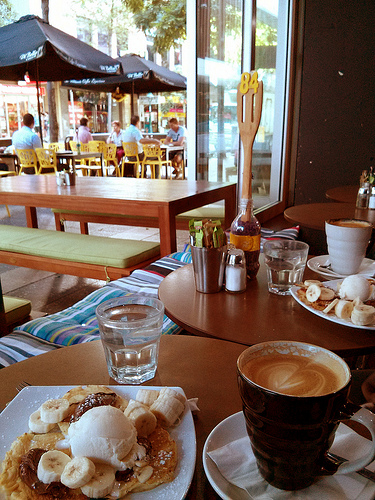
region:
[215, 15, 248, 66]
part of a window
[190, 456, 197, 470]
dgge of a plate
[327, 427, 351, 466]
part of a handle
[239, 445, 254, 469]
aprt of a cloth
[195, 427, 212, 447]
edge of a dish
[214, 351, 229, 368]
part of a table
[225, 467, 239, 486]
edge of a cloth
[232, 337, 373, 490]
A dark coffee mug with light handle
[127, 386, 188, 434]
Banana slices on a white plate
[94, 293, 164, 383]
A clear glass filled with water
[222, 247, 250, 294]
A glass salt shaker with a metal lid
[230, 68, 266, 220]
A tall wood spatula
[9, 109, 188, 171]
People sitting in the background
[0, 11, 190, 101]
A pair of black umbrellas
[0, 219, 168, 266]
A light green cushion on a bench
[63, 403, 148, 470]
A dollop of ice cream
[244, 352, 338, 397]
A pattern in the coffee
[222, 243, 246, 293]
salt and pepper shakers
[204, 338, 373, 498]
napkin sitting between coffee cup and saucer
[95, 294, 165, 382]
glass of water with no ice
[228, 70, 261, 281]
table number with "84" on bakers utencil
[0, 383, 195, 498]
large plate of sweet dessert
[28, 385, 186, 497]
large slices of banana with ice cream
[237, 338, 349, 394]
foaming top to beverage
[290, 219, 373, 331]
second table appears to have ordered the samething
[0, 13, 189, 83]
black umbrellas for outside dinning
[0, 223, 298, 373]
seat cushions on bench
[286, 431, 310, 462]
part of a cup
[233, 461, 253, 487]
part of a cloth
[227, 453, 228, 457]
part of a cloth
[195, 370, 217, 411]
part of a tavle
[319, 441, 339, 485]
part of a handle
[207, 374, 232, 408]
part of a table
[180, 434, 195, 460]
edge of a plate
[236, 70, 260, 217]
wooden spoon in a jar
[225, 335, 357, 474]
cup of cappuccino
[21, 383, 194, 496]
Food on a white plate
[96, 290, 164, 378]
Glass of water on a table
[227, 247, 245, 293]
Salt shaker on a table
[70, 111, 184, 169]
People sitting at a table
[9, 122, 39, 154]
Man wearing a blue shirt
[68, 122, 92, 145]
Man wearing a pink shirt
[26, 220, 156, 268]
green cushion on a bench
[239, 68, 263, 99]
number 84 on a spoon